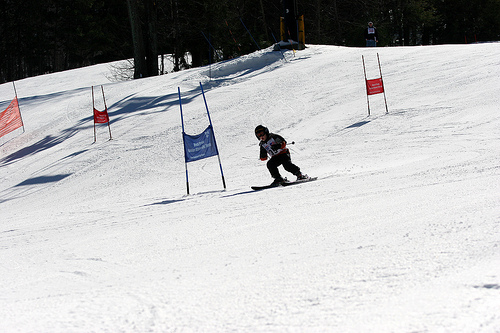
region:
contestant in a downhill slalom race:
[11, 1, 486, 317]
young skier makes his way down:
[242, 120, 318, 195]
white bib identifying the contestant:
[260, 140, 277, 155]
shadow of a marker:
[15, 165, 75, 191]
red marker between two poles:
[355, 47, 390, 117]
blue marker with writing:
[177, 125, 217, 160]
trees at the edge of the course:
[120, 1, 230, 67]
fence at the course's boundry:
[0, 75, 22, 145]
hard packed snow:
[195, 215, 480, 325]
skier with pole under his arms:
[227, 103, 335, 215]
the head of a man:
[228, 113, 280, 158]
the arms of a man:
[251, 127, 293, 171]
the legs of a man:
[253, 153, 302, 187]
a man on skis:
[226, 111, 316, 211]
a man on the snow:
[222, 98, 328, 203]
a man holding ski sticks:
[228, 81, 361, 194]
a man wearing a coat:
[247, 112, 294, 177]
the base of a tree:
[125, 22, 202, 86]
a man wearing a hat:
[247, 108, 289, 150]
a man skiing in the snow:
[220, 58, 368, 205]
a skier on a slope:
[167, 120, 323, 240]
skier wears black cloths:
[249, 115, 314, 189]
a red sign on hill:
[352, 48, 394, 118]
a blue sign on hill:
[171, 77, 231, 195]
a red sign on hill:
[86, 79, 118, 149]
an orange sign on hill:
[0, 77, 26, 147]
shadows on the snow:
[11, 127, 84, 197]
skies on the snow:
[246, 177, 319, 194]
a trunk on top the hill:
[120, 6, 170, 83]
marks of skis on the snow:
[351, 111, 493, 208]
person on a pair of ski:
[245, 113, 319, 194]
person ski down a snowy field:
[226, 103, 339, 209]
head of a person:
[238, 118, 268, 143]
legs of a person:
[260, 152, 310, 182]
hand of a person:
[255, 150, 270, 161]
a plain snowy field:
[51, 253, 388, 330]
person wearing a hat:
[239, 118, 274, 145]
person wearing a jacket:
[234, 100, 322, 195]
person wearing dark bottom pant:
[247, 103, 329, 200]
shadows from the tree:
[209, 40, 289, 89]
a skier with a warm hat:
[239, 120, 325, 198]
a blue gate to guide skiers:
[163, 70, 238, 205]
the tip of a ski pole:
[285, 139, 302, 149]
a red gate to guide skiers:
[85, 76, 127, 154]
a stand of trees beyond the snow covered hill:
[0, 0, 499, 75]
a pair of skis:
[244, 169, 328, 195]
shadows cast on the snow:
[0, 40, 312, 207]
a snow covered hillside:
[2, 39, 497, 331]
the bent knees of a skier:
[257, 158, 302, 173]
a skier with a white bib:
[356, 15, 388, 55]